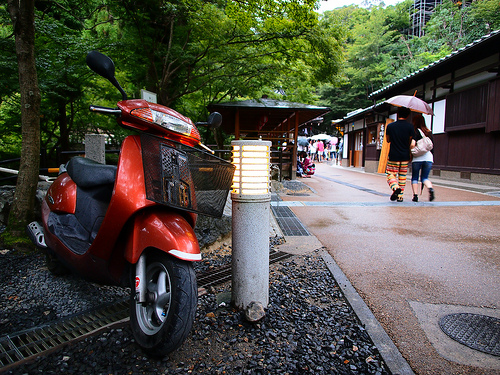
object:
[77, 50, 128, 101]
mirror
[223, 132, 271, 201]
light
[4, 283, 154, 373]
vent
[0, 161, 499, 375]
ground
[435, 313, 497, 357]
grate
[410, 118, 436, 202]
woman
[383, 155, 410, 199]
pants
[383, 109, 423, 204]
man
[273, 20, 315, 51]
leaves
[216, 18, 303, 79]
branches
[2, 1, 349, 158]
trees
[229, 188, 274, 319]
cyclinder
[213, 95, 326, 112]
roof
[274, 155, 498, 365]
walkway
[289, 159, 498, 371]
street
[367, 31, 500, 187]
buildings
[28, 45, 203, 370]
motorcycle is red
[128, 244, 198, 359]
black tire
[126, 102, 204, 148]
headlight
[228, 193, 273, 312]
gray post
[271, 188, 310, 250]
vent on the ground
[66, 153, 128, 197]
black seat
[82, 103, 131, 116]
handlebar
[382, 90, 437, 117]
brown umbrella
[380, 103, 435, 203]
man and woman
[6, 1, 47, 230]
tree trunk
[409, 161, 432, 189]
blue jeans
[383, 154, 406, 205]
long striped pants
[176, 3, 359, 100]
leaves on branches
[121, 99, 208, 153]
unlit scooter headli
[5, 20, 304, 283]
walkway through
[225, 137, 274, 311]
glowing lamp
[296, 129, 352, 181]
group of people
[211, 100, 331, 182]
open structure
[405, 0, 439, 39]
flat building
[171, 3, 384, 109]
trees growing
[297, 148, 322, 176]
woman kneeling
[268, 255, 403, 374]
gravel and gratings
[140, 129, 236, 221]
black metal basket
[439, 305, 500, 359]
black manhole cover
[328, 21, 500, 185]
buildings on side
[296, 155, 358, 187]
end of the street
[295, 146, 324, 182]
person kneeling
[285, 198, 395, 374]
grates next tostreet